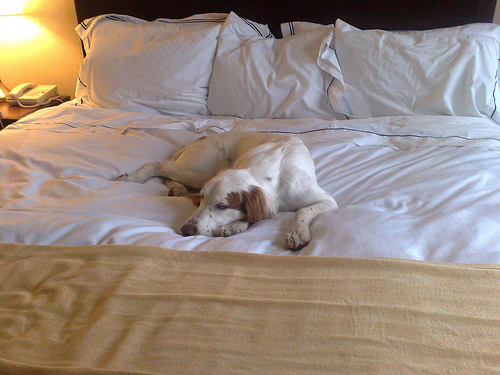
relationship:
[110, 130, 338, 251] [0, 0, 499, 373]
dog laying on bed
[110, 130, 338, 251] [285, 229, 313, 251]
dog has paw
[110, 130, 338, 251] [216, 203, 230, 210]
dog has eye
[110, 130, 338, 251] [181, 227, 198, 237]
dog has nose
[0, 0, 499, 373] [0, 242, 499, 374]
bed has blanket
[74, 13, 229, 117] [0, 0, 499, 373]
pillow on top of bed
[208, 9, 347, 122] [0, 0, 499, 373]
pillow on top of bed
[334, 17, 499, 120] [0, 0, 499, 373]
pillow laying on bed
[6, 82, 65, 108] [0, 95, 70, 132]
phone on top of nightstand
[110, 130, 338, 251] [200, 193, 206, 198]
dog has eye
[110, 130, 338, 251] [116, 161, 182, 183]
dog has leg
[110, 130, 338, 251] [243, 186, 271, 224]
dog has ear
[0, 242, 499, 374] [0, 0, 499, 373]
blanket on top of bed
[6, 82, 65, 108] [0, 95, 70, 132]
phone on nightstand